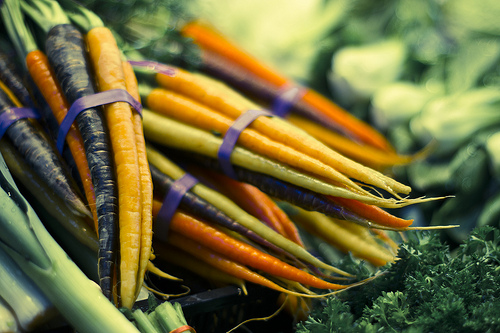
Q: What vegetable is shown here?
A: Carrots.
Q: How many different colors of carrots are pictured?
A: Three.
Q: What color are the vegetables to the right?
A: Green.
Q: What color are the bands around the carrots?
A: Purple.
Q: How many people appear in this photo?
A: Zero.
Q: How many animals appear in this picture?
A: Zero.